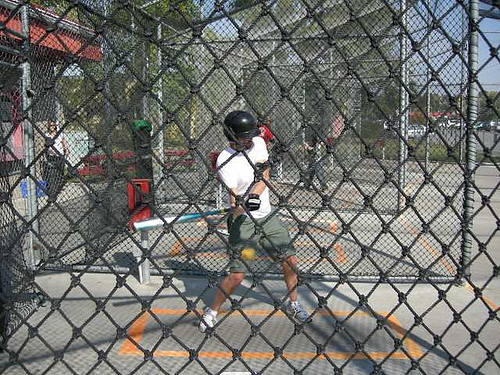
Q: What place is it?
A: It is a field.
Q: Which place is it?
A: It is a field.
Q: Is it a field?
A: Yes, it is a field.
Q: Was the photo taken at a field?
A: Yes, it was taken in a field.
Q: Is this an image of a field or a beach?
A: It is showing a field.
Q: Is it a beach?
A: No, it is a field.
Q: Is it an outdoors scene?
A: Yes, it is outdoors.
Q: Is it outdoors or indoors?
A: It is outdoors.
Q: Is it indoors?
A: No, it is outdoors.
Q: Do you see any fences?
A: Yes, there is a fence.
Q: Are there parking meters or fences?
A: Yes, there is a fence.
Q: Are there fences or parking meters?
A: Yes, there is a fence.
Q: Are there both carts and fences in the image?
A: No, there is a fence but no carts.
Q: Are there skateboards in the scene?
A: No, there are no skateboards.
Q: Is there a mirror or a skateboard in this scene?
A: No, there are no skateboards or mirrors.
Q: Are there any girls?
A: No, there are no girls.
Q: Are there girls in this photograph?
A: No, there are no girls.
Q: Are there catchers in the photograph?
A: No, there are no catchers.